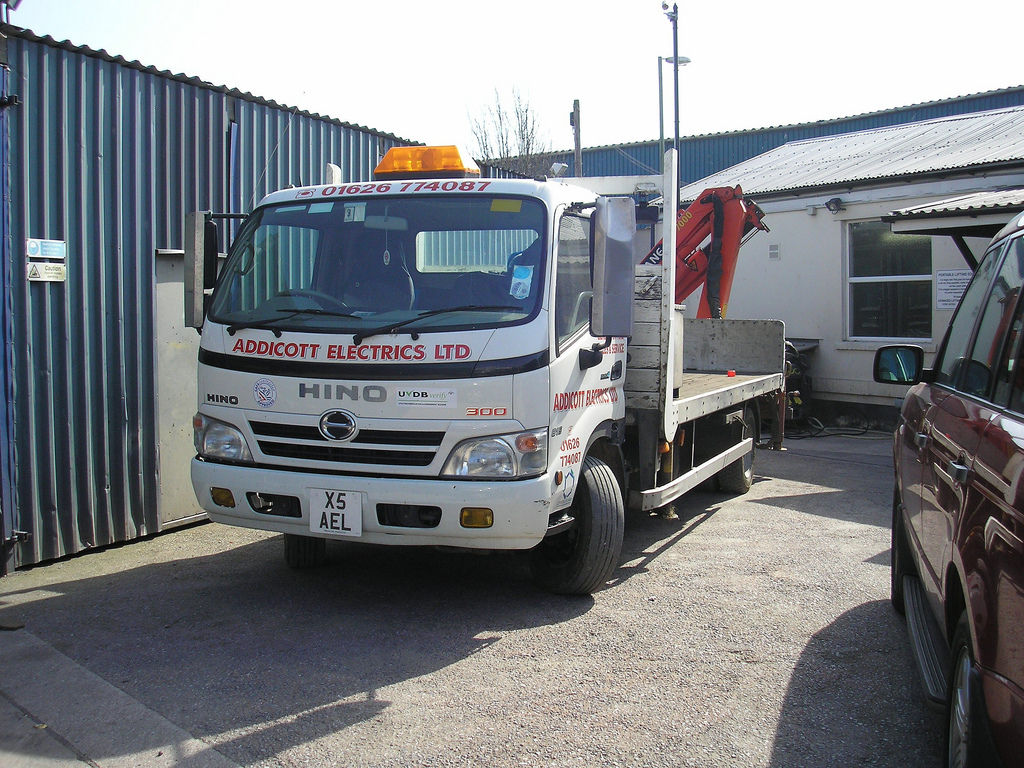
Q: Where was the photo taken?
A: At a tow spot.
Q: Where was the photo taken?
A: In the back yard by the garage.